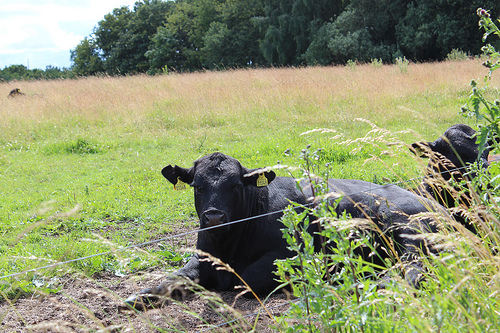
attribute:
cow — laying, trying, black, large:
[155, 152, 466, 296]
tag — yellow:
[254, 173, 269, 187]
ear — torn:
[242, 163, 280, 189]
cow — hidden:
[405, 111, 499, 215]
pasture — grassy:
[3, 56, 499, 332]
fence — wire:
[1, 154, 498, 327]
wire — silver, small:
[0, 157, 497, 281]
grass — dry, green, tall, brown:
[0, 56, 496, 121]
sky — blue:
[4, 3, 139, 69]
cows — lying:
[129, 128, 496, 308]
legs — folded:
[125, 241, 325, 309]